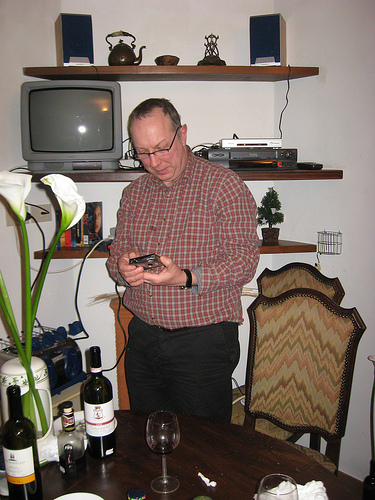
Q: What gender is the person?
A: Male.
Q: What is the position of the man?
A: Standing.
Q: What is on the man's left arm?
A: Watch.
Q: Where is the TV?
A: On the shelf.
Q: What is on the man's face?
A: Glasses.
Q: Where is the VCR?
A: Right side of the TV.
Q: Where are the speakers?
A: Shelf above the TV.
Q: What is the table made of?
A: Wood.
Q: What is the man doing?
A: Looking at camera.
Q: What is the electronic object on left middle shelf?
A: Television.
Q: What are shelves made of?
A: Wood.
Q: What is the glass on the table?
A: Wine glass.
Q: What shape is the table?
A: Round.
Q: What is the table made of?
A: Wood.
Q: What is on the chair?
A: Cloth back.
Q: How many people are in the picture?
A: One.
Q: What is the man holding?
A: A camera.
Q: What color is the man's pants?
A: Black.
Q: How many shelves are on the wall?
A: 3.